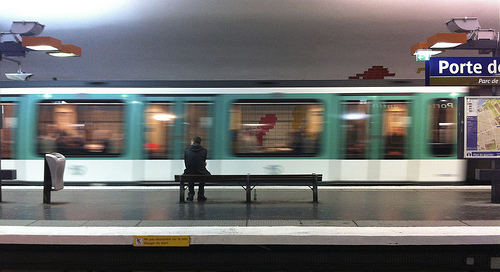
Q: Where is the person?
A: On the bench.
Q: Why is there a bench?
A: For people to sit.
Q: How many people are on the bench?
A: One.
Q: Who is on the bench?
A: The person.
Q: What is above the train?
A: Lights.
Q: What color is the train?
A: Green.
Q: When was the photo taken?
A: As the train was passing.